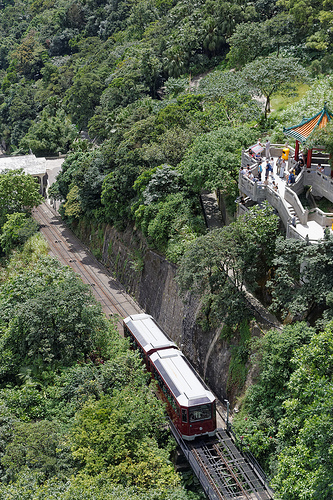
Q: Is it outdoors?
A: Yes, it is outdoors.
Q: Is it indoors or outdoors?
A: It is outdoors.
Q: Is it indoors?
A: No, it is outdoors.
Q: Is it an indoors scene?
A: No, it is outdoors.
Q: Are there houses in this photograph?
A: No, there are no houses.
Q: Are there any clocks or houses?
A: No, there are no houses or clocks.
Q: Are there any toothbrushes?
A: No, there are no toothbrushes.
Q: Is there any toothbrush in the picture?
A: No, there are no toothbrushes.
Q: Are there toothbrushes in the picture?
A: No, there are no toothbrushes.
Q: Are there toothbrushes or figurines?
A: No, there are no toothbrushes or figurines.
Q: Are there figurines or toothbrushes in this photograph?
A: No, there are no toothbrushes or figurines.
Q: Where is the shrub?
A: The shrub is on the hillside.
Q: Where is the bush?
A: The shrub is on the hillside.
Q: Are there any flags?
A: No, there are no flags.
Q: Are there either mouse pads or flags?
A: No, there are no flags or mouse pads.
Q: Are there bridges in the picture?
A: Yes, there is a bridge.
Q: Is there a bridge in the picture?
A: Yes, there is a bridge.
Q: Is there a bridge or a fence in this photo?
A: Yes, there is a bridge.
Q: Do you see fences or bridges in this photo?
A: Yes, there is a bridge.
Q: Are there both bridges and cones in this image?
A: No, there is a bridge but no cones.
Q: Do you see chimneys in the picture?
A: No, there are no chimneys.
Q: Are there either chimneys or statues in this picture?
A: No, there are no chimneys or statues.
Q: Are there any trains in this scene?
A: Yes, there is a train.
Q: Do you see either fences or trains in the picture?
A: Yes, there is a train.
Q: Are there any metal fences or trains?
A: Yes, there is a metal train.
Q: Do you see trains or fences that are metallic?
A: Yes, the train is metallic.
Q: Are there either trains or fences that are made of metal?
A: Yes, the train is made of metal.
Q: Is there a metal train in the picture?
A: Yes, there is a metal train.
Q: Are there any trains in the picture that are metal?
A: Yes, there is a metal train.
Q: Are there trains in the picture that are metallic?
A: Yes, there is a train that is metallic.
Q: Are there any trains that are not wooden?
A: Yes, there is a metallic train.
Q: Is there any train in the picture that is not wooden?
A: Yes, there is a metallic train.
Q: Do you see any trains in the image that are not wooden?
A: Yes, there is a metallic train.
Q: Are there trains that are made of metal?
A: Yes, there is a train that is made of metal.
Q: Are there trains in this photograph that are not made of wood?
A: Yes, there is a train that is made of metal.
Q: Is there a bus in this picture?
A: No, there are no buses.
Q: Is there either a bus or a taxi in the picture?
A: No, there are no buses or taxis.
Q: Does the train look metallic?
A: Yes, the train is metallic.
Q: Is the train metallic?
A: Yes, the train is metallic.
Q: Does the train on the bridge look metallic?
A: Yes, the train is metallic.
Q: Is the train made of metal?
A: Yes, the train is made of metal.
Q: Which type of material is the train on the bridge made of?
A: The train is made of metal.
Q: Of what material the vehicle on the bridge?
A: The train is made of metal.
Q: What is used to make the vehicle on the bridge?
A: The train is made of metal.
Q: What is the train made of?
A: The train is made of metal.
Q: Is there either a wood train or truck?
A: No, there is a train but it is metallic.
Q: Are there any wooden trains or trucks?
A: No, there is a train but it is metallic.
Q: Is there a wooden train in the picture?
A: No, there is a train but it is metallic.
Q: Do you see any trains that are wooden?
A: No, there is a train but it is metallic.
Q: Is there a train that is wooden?
A: No, there is a train but it is metallic.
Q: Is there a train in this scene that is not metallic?
A: No, there is a train but it is metallic.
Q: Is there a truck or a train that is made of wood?
A: No, there is a train but it is made of metal.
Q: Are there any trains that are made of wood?
A: No, there is a train but it is made of metal.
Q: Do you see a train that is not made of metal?
A: No, there is a train but it is made of metal.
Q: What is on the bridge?
A: The train is on the bridge.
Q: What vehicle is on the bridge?
A: The vehicle is a train.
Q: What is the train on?
A: The train is on the bridge.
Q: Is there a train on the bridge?
A: Yes, there is a train on the bridge.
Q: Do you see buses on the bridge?
A: No, there is a train on the bridge.